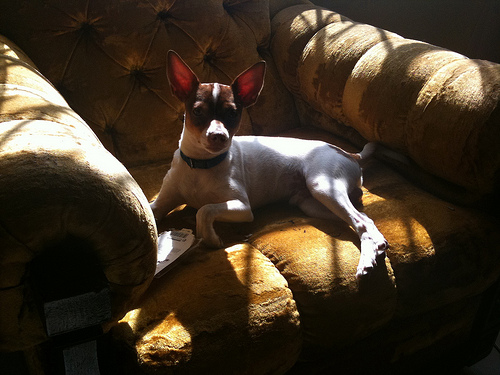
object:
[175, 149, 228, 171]
collar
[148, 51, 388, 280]
dog